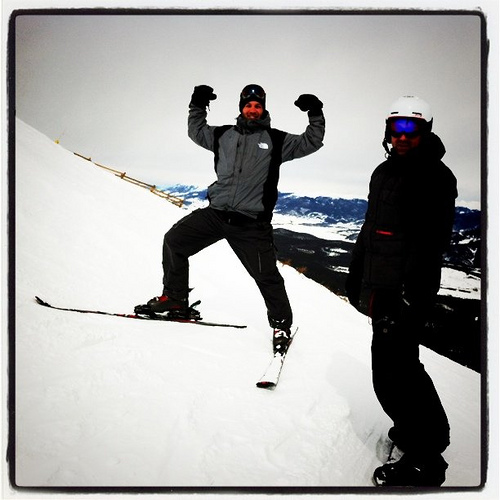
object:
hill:
[27, 108, 158, 237]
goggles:
[387, 120, 423, 139]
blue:
[395, 118, 414, 131]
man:
[346, 95, 460, 488]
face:
[389, 121, 423, 155]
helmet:
[386, 94, 434, 135]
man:
[134, 83, 325, 355]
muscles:
[201, 124, 304, 158]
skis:
[34, 296, 246, 329]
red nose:
[249, 107, 257, 114]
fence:
[70, 151, 185, 210]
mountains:
[102, 177, 481, 389]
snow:
[13, 347, 200, 486]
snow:
[276, 345, 282, 349]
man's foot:
[273, 328, 292, 352]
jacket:
[187, 106, 324, 224]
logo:
[258, 142, 269, 150]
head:
[384, 94, 434, 157]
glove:
[189, 84, 217, 107]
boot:
[133, 294, 189, 319]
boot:
[373, 454, 449, 488]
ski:
[37, 296, 349, 401]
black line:
[261, 127, 287, 214]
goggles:
[240, 89, 266, 99]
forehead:
[245, 93, 262, 101]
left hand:
[293, 95, 323, 113]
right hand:
[189, 84, 218, 106]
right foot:
[133, 296, 189, 318]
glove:
[293, 95, 323, 112]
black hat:
[238, 84, 267, 114]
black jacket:
[345, 129, 460, 320]